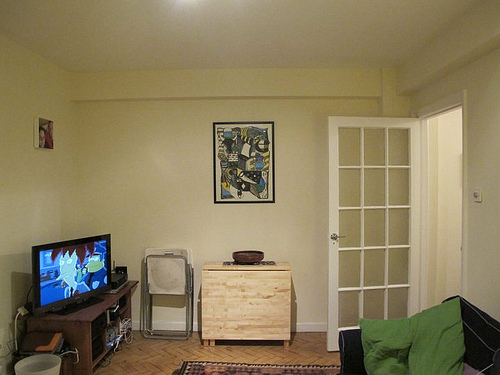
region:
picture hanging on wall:
[208, 118, 283, 205]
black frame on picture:
[213, 126, 273, 198]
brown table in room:
[190, 259, 295, 348]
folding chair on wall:
[136, 248, 193, 344]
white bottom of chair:
[138, 248, 189, 297]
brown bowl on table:
[228, 248, 266, 270]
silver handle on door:
[321, 233, 346, 243]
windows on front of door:
[337, 122, 423, 329]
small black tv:
[28, 232, 118, 314]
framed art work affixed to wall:
[211, 118, 280, 206]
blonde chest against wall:
[200, 260, 297, 348]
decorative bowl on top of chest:
[227, 250, 264, 264]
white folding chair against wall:
[139, 243, 194, 350]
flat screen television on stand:
[31, 226, 115, 313]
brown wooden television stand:
[18, 270, 140, 372]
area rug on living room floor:
[176, 350, 343, 373]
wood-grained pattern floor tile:
[93, 328, 337, 373]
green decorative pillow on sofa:
[354, 294, 467, 374]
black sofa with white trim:
[338, 290, 498, 372]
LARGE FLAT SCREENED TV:
[35, 229, 117, 314]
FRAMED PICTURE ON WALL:
[205, 113, 285, 208]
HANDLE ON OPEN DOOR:
[326, 231, 343, 247]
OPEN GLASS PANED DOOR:
[319, 108, 439, 355]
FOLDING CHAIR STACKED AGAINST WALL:
[133, 245, 200, 345]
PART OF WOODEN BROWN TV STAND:
[65, 318, 90, 342]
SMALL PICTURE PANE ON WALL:
[30, 111, 64, 153]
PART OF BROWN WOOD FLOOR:
[137, 340, 169, 367]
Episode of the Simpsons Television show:
[28, 232, 113, 318]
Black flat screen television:
[25, 230, 115, 320]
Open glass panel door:
[322, 86, 472, 356]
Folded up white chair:
[136, 240, 198, 343]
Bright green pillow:
[355, 294, 467, 374]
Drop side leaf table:
[195, 257, 297, 352]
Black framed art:
[208, 117, 278, 207]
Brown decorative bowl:
[229, 248, 266, 266]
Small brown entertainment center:
[22, 276, 140, 374]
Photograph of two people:
[30, 114, 58, 155]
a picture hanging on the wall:
[203, 112, 284, 209]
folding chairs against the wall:
[136, 240, 197, 343]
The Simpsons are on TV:
[25, 231, 122, 317]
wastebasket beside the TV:
[8, 350, 63, 374]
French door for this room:
[321, 103, 421, 353]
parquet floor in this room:
[106, 325, 329, 370]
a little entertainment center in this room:
[11, 224, 142, 374]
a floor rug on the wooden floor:
[170, 354, 347, 373]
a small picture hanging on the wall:
[31, 109, 61, 156]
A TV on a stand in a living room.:
[30, 232, 112, 318]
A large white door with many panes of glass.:
[324, 111, 421, 354]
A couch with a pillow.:
[335, 291, 496, 371]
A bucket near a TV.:
[13, 345, 63, 371]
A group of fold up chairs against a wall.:
[130, 242, 197, 338]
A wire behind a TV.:
[8, 300, 26, 360]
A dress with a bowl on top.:
[193, 247, 294, 347]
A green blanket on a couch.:
[358, 297, 469, 369]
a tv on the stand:
[30, 216, 115, 302]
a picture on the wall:
[180, 106, 292, 219]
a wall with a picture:
[180, 93, 320, 235]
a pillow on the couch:
[378, 297, 480, 374]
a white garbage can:
[17, 338, 75, 371]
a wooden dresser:
[194, 247, 323, 373]